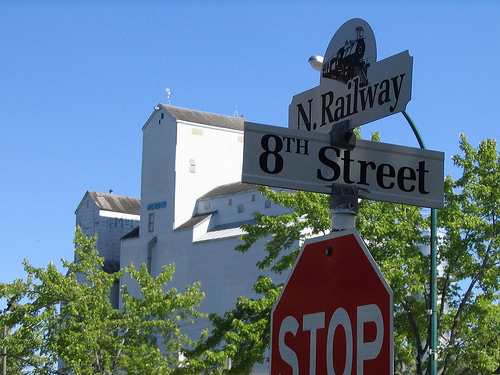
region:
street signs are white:
[216, 31, 485, 233]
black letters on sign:
[265, 61, 446, 207]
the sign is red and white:
[248, 236, 408, 373]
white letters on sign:
[268, 299, 399, 373]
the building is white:
[67, 78, 312, 313]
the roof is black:
[83, 178, 143, 223]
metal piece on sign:
[309, 236, 334, 263]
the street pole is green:
[422, 206, 463, 371]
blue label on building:
[141, 185, 171, 223]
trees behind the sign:
[3, 168, 498, 373]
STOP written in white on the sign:
[286, 250, 389, 370]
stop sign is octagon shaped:
[274, 257, 399, 362]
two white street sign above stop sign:
[249, 51, 430, 207]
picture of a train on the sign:
[321, 29, 381, 73]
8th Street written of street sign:
[254, 138, 429, 195]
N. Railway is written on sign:
[287, 81, 443, 105]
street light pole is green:
[419, 150, 441, 331]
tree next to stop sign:
[128, 270, 270, 365]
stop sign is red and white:
[291, 262, 393, 373]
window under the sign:
[143, 211, 174, 228]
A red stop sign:
[248, 236, 422, 371]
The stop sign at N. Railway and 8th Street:
[232, 35, 471, 365]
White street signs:
[251, 18, 474, 237]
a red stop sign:
[285, 232, 454, 373]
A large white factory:
[67, 85, 238, 370]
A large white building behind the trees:
[65, 91, 250, 366]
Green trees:
[6, 245, 196, 360]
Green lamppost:
[305, 45, 445, 365]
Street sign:
[272, 20, 447, 365]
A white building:
[65, 100, 260, 373]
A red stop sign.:
[243, 216, 410, 357]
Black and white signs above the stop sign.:
[243, 87, 426, 216]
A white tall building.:
[63, 106, 260, 327]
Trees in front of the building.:
[24, 248, 216, 367]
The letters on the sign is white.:
[280, 300, 387, 373]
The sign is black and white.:
[257, 120, 421, 206]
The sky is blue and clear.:
[83, 13, 260, 93]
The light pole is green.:
[408, 138, 454, 373]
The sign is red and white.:
[237, 244, 384, 373]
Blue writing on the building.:
[139, 193, 189, 213]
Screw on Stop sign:
[320, 242, 333, 255]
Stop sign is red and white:
[261, 223, 393, 373]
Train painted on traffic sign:
[312, 20, 367, 82]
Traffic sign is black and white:
[230, 117, 445, 212]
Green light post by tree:
[301, 41, 436, 368]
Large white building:
[55, 96, 435, 371]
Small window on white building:
[231, 200, 241, 211]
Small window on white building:
[225, 190, 231, 205]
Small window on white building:
[250, 190, 255, 201]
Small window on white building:
[260, 195, 271, 206]